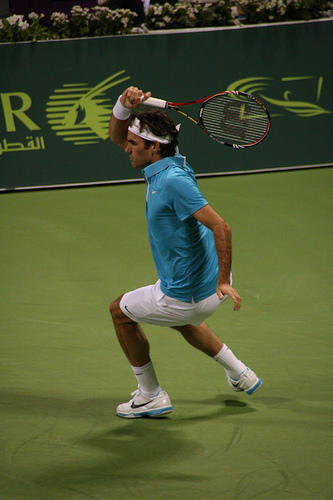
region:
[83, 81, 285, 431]
the man on the court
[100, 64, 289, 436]
the man holding the tennis racquet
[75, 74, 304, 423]
the man playing tennis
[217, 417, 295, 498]
the scuffs on the court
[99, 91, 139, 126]
the band on the wrist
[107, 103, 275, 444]
the man wearing the headband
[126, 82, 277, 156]
the racquet is black red and white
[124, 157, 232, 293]
the man wearing blue polo shirt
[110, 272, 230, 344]
the man wearing white shorts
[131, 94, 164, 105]
the handle of the tennis racquet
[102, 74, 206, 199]
a man playing tennis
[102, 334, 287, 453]
a man wearing nike shoes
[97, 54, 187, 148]
a man wearing a wristband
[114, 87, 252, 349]
a man wearing a blue shirt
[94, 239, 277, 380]
a man wearing nike shorts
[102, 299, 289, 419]
a man wearing white socks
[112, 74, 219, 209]
the head of a man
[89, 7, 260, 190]
a man holding a tennis racket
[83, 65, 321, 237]
a man swinging a tennis racket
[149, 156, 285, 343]
the arm of a man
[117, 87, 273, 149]
Tennis racket with a white grip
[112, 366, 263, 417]
White, blue and black sneakers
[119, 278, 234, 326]
White shorts with a black Nike logo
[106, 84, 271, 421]
Man swinging a racket over his head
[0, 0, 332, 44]
Flowering plants lining the top of the wall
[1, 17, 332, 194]
Green wall with sponser information written on it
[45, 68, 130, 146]
Logo containing an animal with horns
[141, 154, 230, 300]
Blue shirt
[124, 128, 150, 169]
Serious masculine face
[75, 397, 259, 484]
Shadow of a man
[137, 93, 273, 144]
The tennis racket in the player's hand.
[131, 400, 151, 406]
The Nike sign on the player's left sneaker.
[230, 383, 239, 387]
The Nike sign on the player's right sneaker.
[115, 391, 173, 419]
The player's left sneaker.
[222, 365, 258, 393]
The player's right sneaker.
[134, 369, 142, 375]
The Nike sign on the player's left sock.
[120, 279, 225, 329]
The shorts the player is wearing.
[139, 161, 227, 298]
The blue shirt the player is wearing.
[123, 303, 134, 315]
The Nike sign on the player's shorts.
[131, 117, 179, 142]
The white headband on the player's head.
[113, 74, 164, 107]
the hand of a man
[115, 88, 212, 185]
a man wearing a headband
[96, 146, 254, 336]
a man wearing a shirt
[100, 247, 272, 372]
the shorts on a man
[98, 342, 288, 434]
the shoes on a man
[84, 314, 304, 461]
a man wearing tennis shoes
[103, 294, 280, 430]
a man wearing white shorts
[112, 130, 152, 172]
the nose of a man